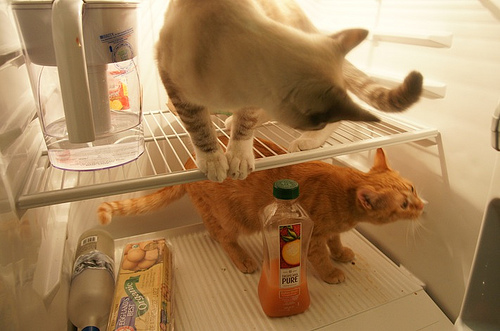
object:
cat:
[153, 0, 423, 183]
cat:
[96, 147, 425, 284]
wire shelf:
[16, 109, 439, 210]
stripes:
[185, 117, 215, 147]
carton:
[107, 237, 172, 331]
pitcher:
[0, 0, 151, 169]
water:
[43, 112, 144, 170]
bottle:
[257, 179, 314, 317]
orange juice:
[257, 258, 310, 318]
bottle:
[68, 228, 114, 330]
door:
[452, 1, 500, 329]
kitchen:
[2, 0, 497, 330]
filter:
[83, 66, 112, 134]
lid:
[273, 179, 300, 200]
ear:
[357, 189, 373, 211]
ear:
[372, 148, 388, 173]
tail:
[343, 59, 423, 113]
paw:
[318, 266, 344, 284]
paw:
[329, 246, 355, 261]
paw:
[236, 257, 257, 273]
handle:
[49, 0, 95, 143]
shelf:
[114, 222, 454, 330]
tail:
[97, 184, 188, 226]